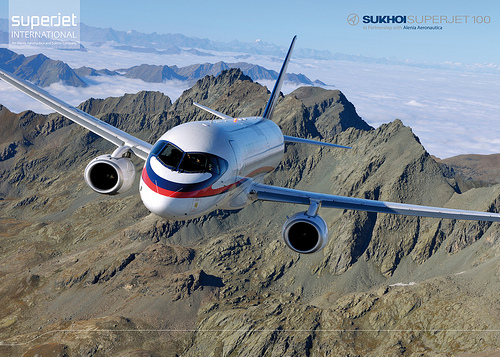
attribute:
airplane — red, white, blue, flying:
[1, 34, 500, 255]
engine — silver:
[283, 208, 327, 257]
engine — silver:
[80, 153, 134, 196]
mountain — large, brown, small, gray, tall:
[3, 66, 497, 356]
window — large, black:
[154, 142, 218, 176]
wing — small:
[249, 180, 499, 223]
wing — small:
[2, 69, 158, 162]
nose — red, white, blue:
[138, 158, 210, 221]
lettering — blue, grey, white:
[358, 12, 500, 31]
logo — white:
[343, 9, 362, 27]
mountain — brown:
[3, 49, 82, 95]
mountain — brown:
[77, 61, 317, 85]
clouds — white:
[1, 71, 305, 114]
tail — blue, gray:
[264, 33, 297, 117]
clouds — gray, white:
[4, 27, 500, 163]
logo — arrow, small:
[63, 104, 106, 126]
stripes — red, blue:
[138, 153, 279, 201]